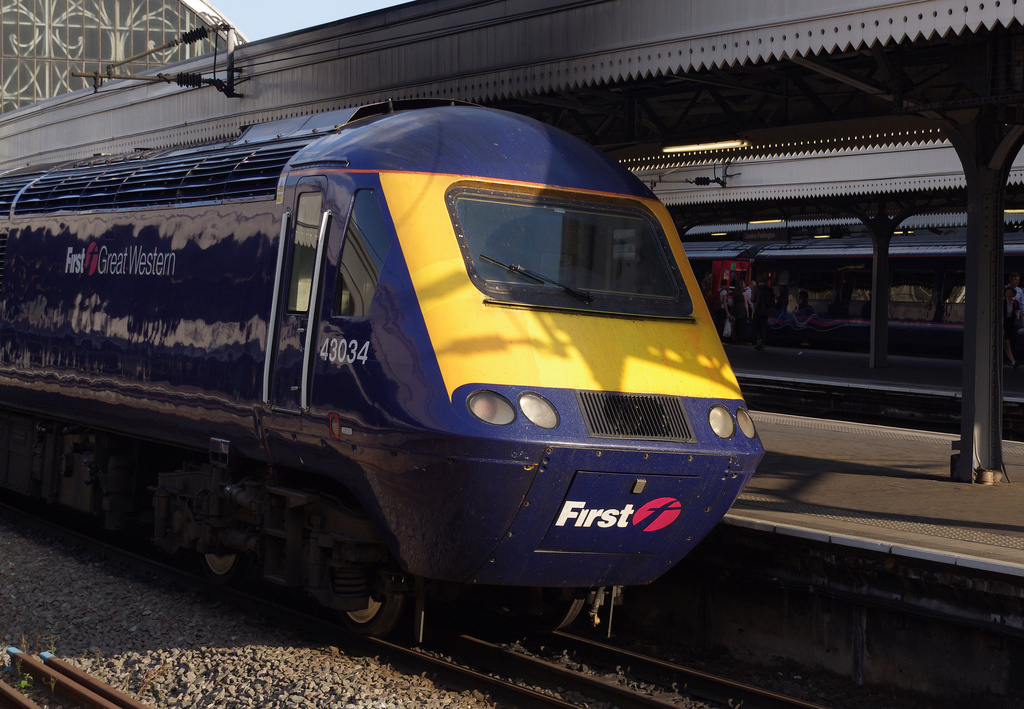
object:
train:
[5, 93, 766, 634]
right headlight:
[705, 402, 738, 439]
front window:
[444, 177, 699, 323]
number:
[320, 338, 375, 365]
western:
[121, 242, 182, 279]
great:
[65, 242, 175, 275]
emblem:
[631, 496, 682, 532]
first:
[555, 500, 634, 528]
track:
[5, 498, 836, 704]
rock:
[90, 655, 383, 695]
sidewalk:
[720, 400, 991, 578]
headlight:
[469, 389, 516, 425]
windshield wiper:
[479, 252, 596, 303]